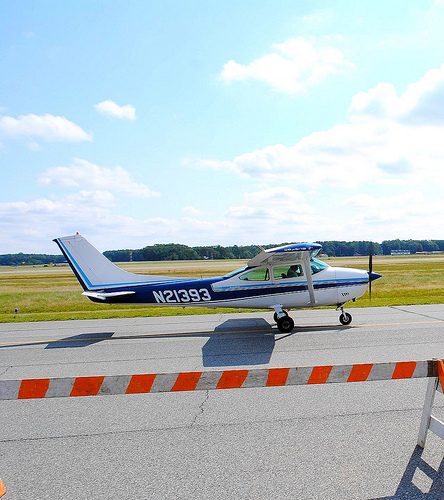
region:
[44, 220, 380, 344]
A man is sitting in the plane.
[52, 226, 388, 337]
The plane is blue and white.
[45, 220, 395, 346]
The plane has three wheels.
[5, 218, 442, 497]
The plane is sitting on tarmac.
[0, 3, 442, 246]
The sky is light blue.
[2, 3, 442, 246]
There are white clouds in the sky.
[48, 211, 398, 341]
Airplane propeller is black.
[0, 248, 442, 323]
The grass is green.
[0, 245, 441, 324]
The grass is short.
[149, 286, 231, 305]
REGISTRATION ON PLANE IS N21393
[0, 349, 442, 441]
ORANGE AND WHITE BARRIER SIGN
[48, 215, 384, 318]
PLANE IS BLUES AND WHITE IN COLOR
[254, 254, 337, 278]
PILOT IS AT THE COCK PIT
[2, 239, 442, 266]
TREES ARE IN THE BACKGROUND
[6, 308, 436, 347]
YELLOW LINE IS UNDER THE PLANE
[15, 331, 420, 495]
GROUND UNDER THE PLANE IS GREY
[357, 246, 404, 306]
PLANE HAS ONE PROPELLER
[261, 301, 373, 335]
THREE WHEELS UNDER THE PLANE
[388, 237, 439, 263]
BUILDINGS ARE TO THE TOP RIGHT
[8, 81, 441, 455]
An airport runway scene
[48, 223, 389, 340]
A single engine airplane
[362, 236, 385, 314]
The plane's propeller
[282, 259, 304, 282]
This is the plane's pilot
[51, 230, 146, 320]
The airplane's tail section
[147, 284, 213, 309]
This is the plane's identification number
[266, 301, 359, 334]
The plane's landing gears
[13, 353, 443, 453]
A sawhorse is along the runway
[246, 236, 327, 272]
One of the plane's wings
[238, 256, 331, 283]
The plane's windows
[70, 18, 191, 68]
a blue sky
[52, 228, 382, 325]
a small air plane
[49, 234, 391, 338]
a blue and white air plane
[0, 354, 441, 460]
a white and orange barrier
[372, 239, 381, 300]
nose of air plane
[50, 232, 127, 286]
tail of air plane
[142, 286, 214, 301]
a letter and numbers on the side of plane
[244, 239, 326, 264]
wing of air plane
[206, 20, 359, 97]
a white cloud in the sky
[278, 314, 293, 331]
a black wheel on air plane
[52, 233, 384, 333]
An airplane on the runway.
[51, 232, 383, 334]
An airplane going to takeoff.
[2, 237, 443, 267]
Lots of green trees.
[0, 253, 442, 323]
A green grassy field.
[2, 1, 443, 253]
A blue and cloudy sky.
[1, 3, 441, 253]
White clouds in the sky.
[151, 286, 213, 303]
Numbers on side of airplane.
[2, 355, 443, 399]
An orange striped board.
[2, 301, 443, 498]
Pavement on an airport runway.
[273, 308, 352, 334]
Three tires on a plane.